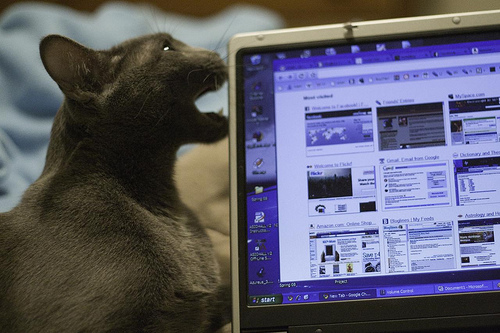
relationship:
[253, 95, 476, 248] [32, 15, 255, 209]
screen near cat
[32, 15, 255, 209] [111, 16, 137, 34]
cat behind fabric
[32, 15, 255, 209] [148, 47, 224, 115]
cat has face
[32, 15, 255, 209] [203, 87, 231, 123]
cat has tooth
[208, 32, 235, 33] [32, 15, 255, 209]
whisker on cat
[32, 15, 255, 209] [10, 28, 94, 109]
cat has ear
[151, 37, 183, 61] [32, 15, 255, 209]
eye of cat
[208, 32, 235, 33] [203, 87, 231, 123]
whisker and tooth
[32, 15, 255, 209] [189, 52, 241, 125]
cat has mouth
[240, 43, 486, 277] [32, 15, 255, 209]
laptop next to cat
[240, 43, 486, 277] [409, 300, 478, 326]
computer has keyboard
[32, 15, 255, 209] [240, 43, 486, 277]
cat next to computer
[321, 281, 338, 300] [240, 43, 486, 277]
google chrome icon on computer